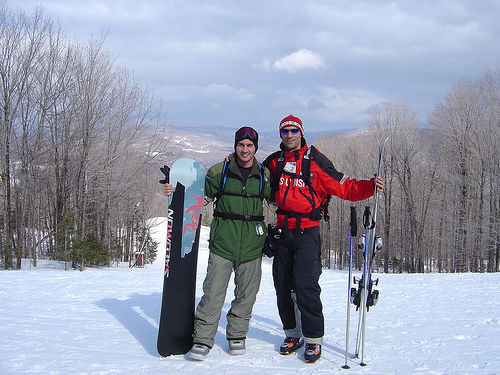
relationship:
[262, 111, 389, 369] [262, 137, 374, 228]
man wearing jacket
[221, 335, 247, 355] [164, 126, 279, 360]
boot worn by man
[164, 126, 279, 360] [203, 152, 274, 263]
man wearing jacket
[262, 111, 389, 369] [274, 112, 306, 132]
man wearing hat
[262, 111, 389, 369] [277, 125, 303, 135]
man wearing sunglasses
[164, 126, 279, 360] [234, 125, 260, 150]
man wearing hat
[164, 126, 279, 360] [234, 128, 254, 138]
man wearing ski goggles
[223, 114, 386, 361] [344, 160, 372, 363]
man with sports equipment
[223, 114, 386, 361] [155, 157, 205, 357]
man with snowboard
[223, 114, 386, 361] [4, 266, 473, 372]
man standing on snow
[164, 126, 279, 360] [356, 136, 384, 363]
man holding skis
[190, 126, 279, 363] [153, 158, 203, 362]
man holding snowboard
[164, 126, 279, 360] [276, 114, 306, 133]
man wearing cap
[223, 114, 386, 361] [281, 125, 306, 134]
man wearing sunglasses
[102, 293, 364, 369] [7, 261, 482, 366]
shadow on snow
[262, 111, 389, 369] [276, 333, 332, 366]
man wearing ski boots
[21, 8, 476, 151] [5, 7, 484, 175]
clouds in sky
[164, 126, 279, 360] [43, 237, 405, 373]
man standing on ski trail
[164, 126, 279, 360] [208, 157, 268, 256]
man dressed in jacket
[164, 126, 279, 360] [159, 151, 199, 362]
man holding snowboard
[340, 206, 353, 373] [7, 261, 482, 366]
pole stuck in snow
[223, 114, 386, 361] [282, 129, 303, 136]
man wearing sunglasses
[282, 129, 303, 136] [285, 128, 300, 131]
sunglasses over eyes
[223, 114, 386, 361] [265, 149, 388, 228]
man dressed in jacket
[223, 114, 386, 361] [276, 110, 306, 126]
man wearing cap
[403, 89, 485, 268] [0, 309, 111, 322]
trees growing along ski trail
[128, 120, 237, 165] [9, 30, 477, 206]
mountains rising in distance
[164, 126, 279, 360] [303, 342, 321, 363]
man wearing ski boots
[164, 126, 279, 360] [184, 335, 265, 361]
man wearing boots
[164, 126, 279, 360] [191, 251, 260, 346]
man wearing trousers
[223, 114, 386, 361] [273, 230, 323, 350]
man wearing pants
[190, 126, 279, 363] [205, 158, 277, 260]
man wearing jacket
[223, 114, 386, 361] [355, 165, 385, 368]
man holding skis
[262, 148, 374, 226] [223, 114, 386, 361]
jacket worn by man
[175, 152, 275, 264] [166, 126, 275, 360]
jacket worn by human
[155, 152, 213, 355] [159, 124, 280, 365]
snowboard held by human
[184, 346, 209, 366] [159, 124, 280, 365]
boot worn by human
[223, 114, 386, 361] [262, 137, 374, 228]
man in a jacket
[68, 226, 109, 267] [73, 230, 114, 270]
bush with leaves